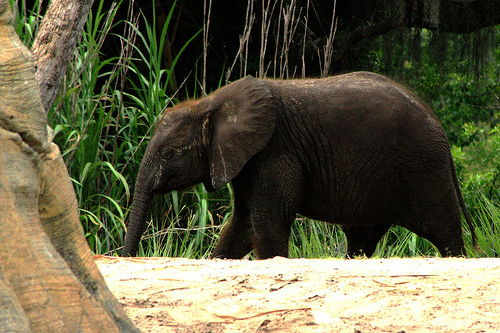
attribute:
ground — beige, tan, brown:
[100, 257, 499, 328]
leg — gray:
[249, 202, 289, 258]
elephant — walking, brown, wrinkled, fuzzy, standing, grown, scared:
[123, 72, 479, 258]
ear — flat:
[207, 74, 275, 191]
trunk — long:
[122, 153, 153, 260]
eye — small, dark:
[160, 150, 177, 158]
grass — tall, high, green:
[459, 186, 499, 258]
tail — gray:
[447, 136, 480, 254]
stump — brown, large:
[0, 19, 141, 331]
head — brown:
[143, 98, 214, 192]